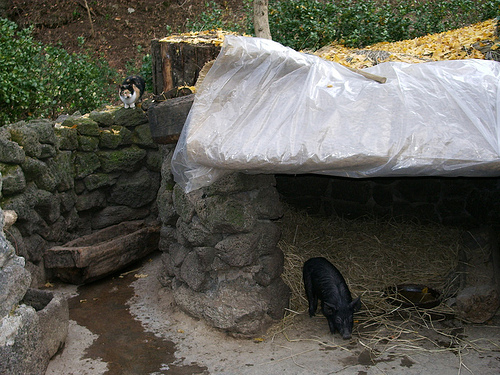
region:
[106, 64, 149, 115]
a orange, white and black cat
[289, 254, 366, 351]
a small black pig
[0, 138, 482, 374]
a pig in a rock enclosure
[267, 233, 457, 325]
hay on the ground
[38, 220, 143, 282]
a rock feeding troft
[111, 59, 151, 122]
a cat sitting on a rock wall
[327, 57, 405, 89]
a stick on a piece of plastic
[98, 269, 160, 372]
water on a cement floor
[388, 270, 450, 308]
a black feeding bowl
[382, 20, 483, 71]
yellow leaves on the ground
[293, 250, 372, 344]
the boar is black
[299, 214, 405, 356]
the boar is black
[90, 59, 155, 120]
a cat on a stone wall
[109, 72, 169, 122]
a cat on a stone wall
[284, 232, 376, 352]
pig in a stone cave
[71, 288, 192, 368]
water leaked on the ground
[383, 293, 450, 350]
hay on the ground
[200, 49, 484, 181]
tarp on a stone wall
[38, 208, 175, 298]
water container on the ground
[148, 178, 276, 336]
stone wall by pig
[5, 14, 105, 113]
green leaves of a bush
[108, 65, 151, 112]
dog in the mulch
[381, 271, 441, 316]
bowl of water for a pig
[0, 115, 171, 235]
stone wall in the back of pig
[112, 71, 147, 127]
cat standing on wall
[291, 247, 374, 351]
pig standing on hay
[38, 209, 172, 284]
food trough for a pig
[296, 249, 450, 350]
pig and his water bowl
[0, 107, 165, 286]
rock wall and trough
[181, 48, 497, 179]
plastic covering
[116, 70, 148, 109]
brown white and black cat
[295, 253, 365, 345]
black pig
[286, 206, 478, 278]
hay for a pig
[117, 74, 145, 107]
cat overlooking a pig's home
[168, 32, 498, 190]
white plastic tarp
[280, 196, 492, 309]
yellow hay under the cave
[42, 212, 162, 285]
stone water basin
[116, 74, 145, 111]
brown, white, and black cat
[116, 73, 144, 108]
furry cat watching pig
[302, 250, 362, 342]
black pig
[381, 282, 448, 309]
water bowl in the hay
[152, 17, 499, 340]
plastic and stone cave for pig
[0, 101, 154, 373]
grey stone wall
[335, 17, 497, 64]
dried yellow leaves above cave